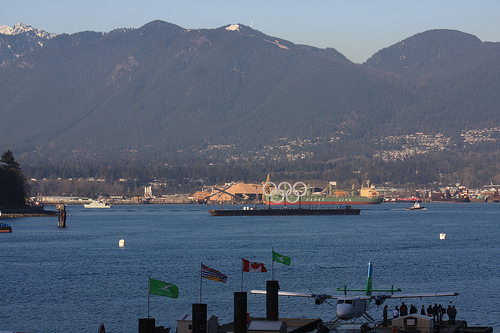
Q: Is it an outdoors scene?
A: Yes, it is outdoors.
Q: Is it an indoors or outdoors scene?
A: It is outdoors.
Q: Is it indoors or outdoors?
A: It is outdoors.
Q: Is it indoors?
A: No, it is outdoors.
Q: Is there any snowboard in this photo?
A: No, there are no snowboards.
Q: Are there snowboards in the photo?
A: No, there are no snowboards.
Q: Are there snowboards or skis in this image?
A: No, there are no snowboards or skis.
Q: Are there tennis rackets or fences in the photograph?
A: No, there are no fences or tennis rackets.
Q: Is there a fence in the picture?
A: No, there are no fences.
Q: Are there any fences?
A: No, there are no fences.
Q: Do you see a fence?
A: No, there are no fences.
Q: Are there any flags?
A: Yes, there is a flag.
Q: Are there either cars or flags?
A: Yes, there is a flag.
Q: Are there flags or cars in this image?
A: Yes, there is a flag.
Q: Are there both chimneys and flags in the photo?
A: No, there is a flag but no chimneys.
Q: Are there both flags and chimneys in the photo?
A: No, there is a flag but no chimneys.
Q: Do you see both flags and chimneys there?
A: No, there is a flag but no chimneys.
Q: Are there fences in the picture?
A: No, there are no fences.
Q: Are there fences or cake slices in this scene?
A: No, there are no fences or cake slices.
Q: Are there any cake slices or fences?
A: No, there are no fences or cake slices.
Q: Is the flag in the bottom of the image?
A: Yes, the flag is in the bottom of the image.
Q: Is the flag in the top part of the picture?
A: No, the flag is in the bottom of the image.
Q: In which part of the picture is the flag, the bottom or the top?
A: The flag is in the bottom of the image.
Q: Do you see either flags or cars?
A: Yes, there is a flag.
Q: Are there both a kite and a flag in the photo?
A: No, there is a flag but no kites.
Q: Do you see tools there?
A: No, there are no tools.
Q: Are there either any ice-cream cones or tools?
A: No, there are no tools or ice-cream cones.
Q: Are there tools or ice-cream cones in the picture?
A: No, there are no tools or ice-cream cones.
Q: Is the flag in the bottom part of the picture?
A: Yes, the flag is in the bottom of the image.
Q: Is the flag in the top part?
A: No, the flag is in the bottom of the image.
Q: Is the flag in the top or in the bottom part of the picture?
A: The flag is in the bottom of the image.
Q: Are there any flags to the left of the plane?
A: Yes, there is a flag to the left of the plane.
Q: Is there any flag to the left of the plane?
A: Yes, there is a flag to the left of the plane.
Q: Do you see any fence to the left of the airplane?
A: No, there is a flag to the left of the airplane.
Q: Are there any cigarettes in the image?
A: No, there are no cigarettes.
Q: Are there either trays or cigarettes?
A: No, there are no cigarettes or trays.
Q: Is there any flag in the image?
A: Yes, there is a flag.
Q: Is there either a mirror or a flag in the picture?
A: Yes, there is a flag.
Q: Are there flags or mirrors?
A: Yes, there is a flag.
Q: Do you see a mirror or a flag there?
A: Yes, there is a flag.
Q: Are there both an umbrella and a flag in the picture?
A: No, there is a flag but no umbrellas.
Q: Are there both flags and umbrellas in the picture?
A: No, there is a flag but no umbrellas.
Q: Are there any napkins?
A: No, there are no napkins.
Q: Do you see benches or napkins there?
A: No, there are no napkins or benches.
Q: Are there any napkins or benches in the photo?
A: No, there are no napkins or benches.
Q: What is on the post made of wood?
A: The flag is on the post.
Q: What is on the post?
A: The flag is on the post.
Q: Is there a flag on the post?
A: Yes, there is a flag on the post.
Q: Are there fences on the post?
A: No, there is a flag on the post.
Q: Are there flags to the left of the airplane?
A: Yes, there is a flag to the left of the airplane.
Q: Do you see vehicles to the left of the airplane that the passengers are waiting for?
A: No, there is a flag to the left of the plane.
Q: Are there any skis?
A: No, there are no skis.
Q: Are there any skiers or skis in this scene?
A: No, there are no skis or skiers.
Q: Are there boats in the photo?
A: Yes, there is a boat.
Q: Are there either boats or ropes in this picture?
A: Yes, there is a boat.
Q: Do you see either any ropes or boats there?
A: Yes, there is a boat.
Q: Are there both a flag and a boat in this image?
A: Yes, there are both a boat and a flag.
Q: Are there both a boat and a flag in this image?
A: Yes, there are both a boat and a flag.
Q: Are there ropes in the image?
A: No, there are no ropes.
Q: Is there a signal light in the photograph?
A: No, there are no traffic lights.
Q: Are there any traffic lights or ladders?
A: No, there are no traffic lights or ladders.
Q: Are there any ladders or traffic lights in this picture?
A: No, there are no traffic lights or ladders.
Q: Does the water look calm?
A: Yes, the water is calm.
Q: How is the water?
A: The water is calm.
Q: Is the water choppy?
A: No, the water is calm.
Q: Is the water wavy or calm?
A: The water is calm.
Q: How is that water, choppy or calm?
A: The water is calm.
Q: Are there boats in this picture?
A: Yes, there is a boat.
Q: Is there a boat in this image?
A: Yes, there is a boat.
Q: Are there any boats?
A: Yes, there is a boat.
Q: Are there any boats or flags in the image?
A: Yes, there is a boat.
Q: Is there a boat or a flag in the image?
A: Yes, there is a boat.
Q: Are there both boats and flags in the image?
A: Yes, there are both a boat and a flag.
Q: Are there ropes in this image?
A: No, there are no ropes.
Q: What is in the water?
A: The boat is in the water.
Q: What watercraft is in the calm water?
A: The watercraft is a boat.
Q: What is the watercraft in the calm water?
A: The watercraft is a boat.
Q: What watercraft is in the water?
A: The watercraft is a boat.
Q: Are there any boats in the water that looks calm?
A: Yes, there is a boat in the water.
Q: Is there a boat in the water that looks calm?
A: Yes, there is a boat in the water.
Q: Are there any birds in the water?
A: No, there is a boat in the water.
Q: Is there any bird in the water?
A: No, there is a boat in the water.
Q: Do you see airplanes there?
A: Yes, there is an airplane.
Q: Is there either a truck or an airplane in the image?
A: Yes, there is an airplane.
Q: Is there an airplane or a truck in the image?
A: Yes, there is an airplane.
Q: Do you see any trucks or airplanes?
A: Yes, there is an airplane.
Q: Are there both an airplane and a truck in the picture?
A: No, there is an airplane but no trucks.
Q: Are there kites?
A: No, there are no kites.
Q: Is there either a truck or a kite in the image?
A: No, there are no kites or trucks.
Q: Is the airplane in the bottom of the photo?
A: Yes, the airplane is in the bottom of the image.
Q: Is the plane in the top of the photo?
A: No, the plane is in the bottom of the image.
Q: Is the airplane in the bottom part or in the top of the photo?
A: The airplane is in the bottom of the image.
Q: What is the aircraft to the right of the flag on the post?
A: The aircraft is an airplane.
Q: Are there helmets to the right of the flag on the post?
A: No, there is an airplane to the right of the flag.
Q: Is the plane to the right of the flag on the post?
A: Yes, the plane is to the right of the flag.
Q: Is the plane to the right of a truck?
A: No, the plane is to the right of the flag.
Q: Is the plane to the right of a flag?
A: Yes, the plane is to the right of a flag.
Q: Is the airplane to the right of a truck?
A: No, the airplane is to the right of a flag.